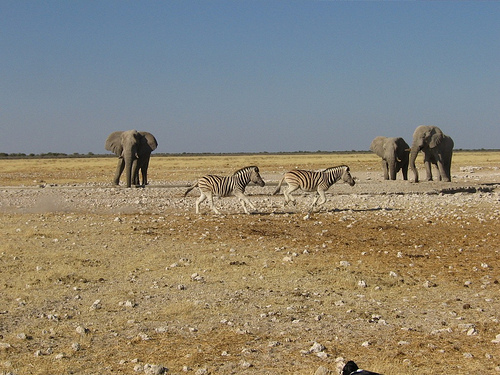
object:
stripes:
[209, 177, 236, 193]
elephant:
[104, 128, 158, 189]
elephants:
[409, 124, 453, 182]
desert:
[0, 152, 499, 375]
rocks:
[0, 175, 500, 375]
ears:
[105, 130, 157, 158]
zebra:
[272, 164, 356, 204]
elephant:
[369, 135, 411, 179]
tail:
[183, 182, 198, 199]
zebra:
[180, 166, 266, 219]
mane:
[233, 165, 256, 176]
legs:
[284, 181, 299, 198]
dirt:
[288, 171, 307, 190]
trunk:
[121, 145, 136, 189]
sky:
[2, 0, 499, 153]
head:
[105, 130, 158, 189]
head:
[338, 165, 356, 187]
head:
[249, 165, 266, 187]